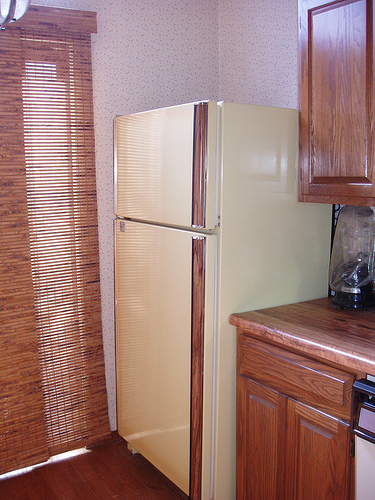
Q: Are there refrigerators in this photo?
A: Yes, there is a refrigerator.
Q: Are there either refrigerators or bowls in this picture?
A: Yes, there is a refrigerator.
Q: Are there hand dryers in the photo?
A: No, there are no hand dryers.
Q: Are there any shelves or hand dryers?
A: No, there are no hand dryers or shelves.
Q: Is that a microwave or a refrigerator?
A: That is a refrigerator.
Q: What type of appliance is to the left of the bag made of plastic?
A: The appliance is a refrigerator.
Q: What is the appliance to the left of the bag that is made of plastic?
A: The appliance is a refrigerator.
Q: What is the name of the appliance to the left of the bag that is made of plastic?
A: The appliance is a refrigerator.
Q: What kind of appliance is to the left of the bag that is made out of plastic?
A: The appliance is a refrigerator.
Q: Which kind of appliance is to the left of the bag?
A: The appliance is a refrigerator.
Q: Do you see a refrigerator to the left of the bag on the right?
A: Yes, there is a refrigerator to the left of the bag.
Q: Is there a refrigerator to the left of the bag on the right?
A: Yes, there is a refrigerator to the left of the bag.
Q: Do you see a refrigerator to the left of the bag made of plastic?
A: Yes, there is a refrigerator to the left of the bag.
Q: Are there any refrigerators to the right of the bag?
A: No, the refrigerator is to the left of the bag.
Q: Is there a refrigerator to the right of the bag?
A: No, the refrigerator is to the left of the bag.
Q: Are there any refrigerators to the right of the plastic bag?
A: No, the refrigerator is to the left of the bag.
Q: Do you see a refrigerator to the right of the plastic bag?
A: No, the refrigerator is to the left of the bag.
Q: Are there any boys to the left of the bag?
A: No, there is a refrigerator to the left of the bag.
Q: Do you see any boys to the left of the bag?
A: No, there is a refrigerator to the left of the bag.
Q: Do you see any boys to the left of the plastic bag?
A: No, there is a refrigerator to the left of the bag.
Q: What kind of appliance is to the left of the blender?
A: The appliance is a refrigerator.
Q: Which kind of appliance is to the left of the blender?
A: The appliance is a refrigerator.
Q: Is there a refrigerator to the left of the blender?
A: Yes, there is a refrigerator to the left of the blender.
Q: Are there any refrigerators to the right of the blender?
A: No, the refrigerator is to the left of the blender.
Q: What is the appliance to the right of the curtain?
A: The appliance is a refrigerator.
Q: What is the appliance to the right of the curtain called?
A: The appliance is a refrigerator.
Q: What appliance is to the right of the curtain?
A: The appliance is a refrigerator.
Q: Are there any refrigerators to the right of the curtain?
A: Yes, there is a refrigerator to the right of the curtain.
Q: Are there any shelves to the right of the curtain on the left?
A: No, there is a refrigerator to the right of the curtain.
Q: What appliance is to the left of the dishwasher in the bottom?
A: The appliance is a refrigerator.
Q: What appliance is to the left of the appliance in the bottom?
A: The appliance is a refrigerator.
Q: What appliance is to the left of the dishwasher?
A: The appliance is a refrigerator.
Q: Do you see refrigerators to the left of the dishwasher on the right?
A: Yes, there is a refrigerator to the left of the dishwasher.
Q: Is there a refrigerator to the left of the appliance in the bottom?
A: Yes, there is a refrigerator to the left of the dishwasher.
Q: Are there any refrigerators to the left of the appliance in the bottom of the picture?
A: Yes, there is a refrigerator to the left of the dishwasher.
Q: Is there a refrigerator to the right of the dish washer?
A: No, the refrigerator is to the left of the dish washer.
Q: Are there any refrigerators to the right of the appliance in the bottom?
A: No, the refrigerator is to the left of the dish washer.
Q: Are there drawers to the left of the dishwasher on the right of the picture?
A: No, there is a refrigerator to the left of the dishwasher.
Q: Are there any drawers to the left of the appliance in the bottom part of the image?
A: No, there is a refrigerator to the left of the dishwasher.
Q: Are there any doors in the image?
A: Yes, there is a door.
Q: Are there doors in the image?
A: Yes, there is a door.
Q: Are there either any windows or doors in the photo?
A: Yes, there is a door.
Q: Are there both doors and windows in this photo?
A: Yes, there are both a door and a window.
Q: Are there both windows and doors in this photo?
A: Yes, there are both a door and a window.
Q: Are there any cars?
A: No, there are no cars.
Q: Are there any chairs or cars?
A: No, there are no cars or chairs.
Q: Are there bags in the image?
A: Yes, there is a bag.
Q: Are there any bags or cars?
A: Yes, there is a bag.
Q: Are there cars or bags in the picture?
A: Yes, there is a bag.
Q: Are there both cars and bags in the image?
A: No, there is a bag but no cars.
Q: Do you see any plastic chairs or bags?
A: Yes, there is a plastic bag.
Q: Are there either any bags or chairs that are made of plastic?
A: Yes, the bag is made of plastic.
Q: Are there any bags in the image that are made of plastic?
A: Yes, there is a bag that is made of plastic.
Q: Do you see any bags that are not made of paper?
A: Yes, there is a bag that is made of plastic.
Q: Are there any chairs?
A: No, there are no chairs.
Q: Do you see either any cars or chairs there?
A: No, there are no chairs or cars.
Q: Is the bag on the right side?
A: Yes, the bag is on the right of the image.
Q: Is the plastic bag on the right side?
A: Yes, the bag is on the right of the image.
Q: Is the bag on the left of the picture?
A: No, the bag is on the right of the image.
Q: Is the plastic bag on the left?
A: No, the bag is on the right of the image.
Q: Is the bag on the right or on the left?
A: The bag is on the right of the image.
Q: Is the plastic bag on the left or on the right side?
A: The bag is on the right of the image.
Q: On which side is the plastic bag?
A: The bag is on the right of the image.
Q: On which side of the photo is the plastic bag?
A: The bag is on the right of the image.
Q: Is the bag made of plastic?
A: Yes, the bag is made of plastic.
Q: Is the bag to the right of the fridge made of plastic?
A: Yes, the bag is made of plastic.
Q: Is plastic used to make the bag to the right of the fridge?
A: Yes, the bag is made of plastic.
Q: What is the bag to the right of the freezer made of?
A: The bag is made of plastic.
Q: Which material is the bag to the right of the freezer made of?
A: The bag is made of plastic.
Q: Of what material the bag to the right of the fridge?
A: The bag is made of plastic.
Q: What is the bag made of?
A: The bag is made of plastic.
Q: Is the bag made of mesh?
A: No, the bag is made of plastic.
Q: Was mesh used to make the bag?
A: No, the bag is made of plastic.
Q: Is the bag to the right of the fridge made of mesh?
A: No, the bag is made of plastic.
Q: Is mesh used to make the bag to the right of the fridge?
A: No, the bag is made of plastic.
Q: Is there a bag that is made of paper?
A: No, there is a bag but it is made of plastic.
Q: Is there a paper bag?
A: No, there is a bag but it is made of plastic.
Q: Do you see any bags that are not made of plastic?
A: No, there is a bag but it is made of plastic.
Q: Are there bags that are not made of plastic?
A: No, there is a bag but it is made of plastic.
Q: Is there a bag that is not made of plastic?
A: No, there is a bag but it is made of plastic.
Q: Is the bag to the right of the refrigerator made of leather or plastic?
A: The bag is made of plastic.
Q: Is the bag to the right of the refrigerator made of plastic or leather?
A: The bag is made of plastic.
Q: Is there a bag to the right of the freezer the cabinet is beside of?
A: Yes, there is a bag to the right of the refrigerator.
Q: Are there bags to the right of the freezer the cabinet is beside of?
A: Yes, there is a bag to the right of the refrigerator.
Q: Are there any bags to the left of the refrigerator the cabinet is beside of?
A: No, the bag is to the right of the refrigerator.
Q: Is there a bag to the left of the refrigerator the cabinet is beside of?
A: No, the bag is to the right of the refrigerator.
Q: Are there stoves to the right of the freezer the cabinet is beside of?
A: No, there is a bag to the right of the fridge.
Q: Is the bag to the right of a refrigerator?
A: Yes, the bag is to the right of a refrigerator.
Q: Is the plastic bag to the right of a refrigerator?
A: Yes, the bag is to the right of a refrigerator.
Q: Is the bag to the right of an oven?
A: No, the bag is to the right of a refrigerator.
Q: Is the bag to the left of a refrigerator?
A: No, the bag is to the right of a refrigerator.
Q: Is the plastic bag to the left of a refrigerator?
A: No, the bag is to the right of a refrigerator.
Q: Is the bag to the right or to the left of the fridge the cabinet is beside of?
A: The bag is to the right of the refrigerator.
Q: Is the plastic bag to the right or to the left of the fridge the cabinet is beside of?
A: The bag is to the right of the refrigerator.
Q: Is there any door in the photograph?
A: Yes, there is a door.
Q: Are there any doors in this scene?
A: Yes, there is a door.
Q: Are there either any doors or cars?
A: Yes, there is a door.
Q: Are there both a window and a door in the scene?
A: Yes, there are both a door and a window.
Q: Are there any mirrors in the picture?
A: No, there are no mirrors.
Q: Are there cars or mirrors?
A: No, there are no mirrors or cars.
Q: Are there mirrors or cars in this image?
A: No, there are no mirrors or cars.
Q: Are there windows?
A: Yes, there is a window.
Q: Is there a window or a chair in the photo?
A: Yes, there is a window.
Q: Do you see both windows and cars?
A: No, there is a window but no cars.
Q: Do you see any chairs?
A: No, there are no chairs.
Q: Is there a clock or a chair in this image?
A: No, there are no chairs or clocks.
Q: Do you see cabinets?
A: Yes, there is a cabinet.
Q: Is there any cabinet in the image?
A: Yes, there is a cabinet.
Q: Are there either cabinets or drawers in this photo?
A: Yes, there is a cabinet.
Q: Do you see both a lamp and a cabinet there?
A: No, there is a cabinet but no lamps.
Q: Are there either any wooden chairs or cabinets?
A: Yes, there is a wood cabinet.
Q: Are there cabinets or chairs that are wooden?
A: Yes, the cabinet is wooden.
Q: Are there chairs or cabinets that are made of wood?
A: Yes, the cabinet is made of wood.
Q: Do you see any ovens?
A: No, there are no ovens.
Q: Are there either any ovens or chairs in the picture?
A: No, there are no ovens or chairs.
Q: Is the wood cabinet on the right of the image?
A: Yes, the cabinet is on the right of the image.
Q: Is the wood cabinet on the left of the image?
A: No, the cabinet is on the right of the image.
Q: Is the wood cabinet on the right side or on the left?
A: The cabinet is on the right of the image.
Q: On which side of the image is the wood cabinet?
A: The cabinet is on the right of the image.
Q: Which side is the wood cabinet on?
A: The cabinet is on the right of the image.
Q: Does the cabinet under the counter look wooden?
A: Yes, the cabinet is wooden.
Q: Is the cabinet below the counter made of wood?
A: Yes, the cabinet is made of wood.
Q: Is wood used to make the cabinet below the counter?
A: Yes, the cabinet is made of wood.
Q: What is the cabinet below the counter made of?
A: The cabinet is made of wood.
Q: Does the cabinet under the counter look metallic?
A: No, the cabinet is wooden.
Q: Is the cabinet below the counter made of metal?
A: No, the cabinet is made of wood.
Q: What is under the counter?
A: The cabinet is under the counter.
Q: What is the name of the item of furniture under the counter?
A: The piece of furniture is a cabinet.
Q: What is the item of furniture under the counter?
A: The piece of furniture is a cabinet.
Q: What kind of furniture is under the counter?
A: The piece of furniture is a cabinet.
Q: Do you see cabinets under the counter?
A: Yes, there is a cabinet under the counter.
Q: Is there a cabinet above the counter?
A: No, the cabinet is under the counter.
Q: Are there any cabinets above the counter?
A: No, the cabinet is under the counter.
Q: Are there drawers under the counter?
A: No, there is a cabinet under the counter.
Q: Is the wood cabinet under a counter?
A: Yes, the cabinet is under a counter.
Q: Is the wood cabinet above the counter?
A: No, the cabinet is under the counter.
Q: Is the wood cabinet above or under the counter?
A: The cabinet is under the counter.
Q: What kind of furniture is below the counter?
A: The piece of furniture is a cabinet.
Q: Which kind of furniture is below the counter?
A: The piece of furniture is a cabinet.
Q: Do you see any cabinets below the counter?
A: Yes, there is a cabinet below the counter.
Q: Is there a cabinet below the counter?
A: Yes, there is a cabinet below the counter.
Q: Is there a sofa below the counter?
A: No, there is a cabinet below the counter.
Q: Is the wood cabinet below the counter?
A: Yes, the cabinet is below the counter.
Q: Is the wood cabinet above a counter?
A: No, the cabinet is below a counter.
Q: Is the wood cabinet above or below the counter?
A: The cabinet is below the counter.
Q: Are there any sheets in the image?
A: No, there are no sheets.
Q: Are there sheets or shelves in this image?
A: No, there are no sheets or shelves.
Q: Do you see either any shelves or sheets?
A: No, there are no sheets or shelves.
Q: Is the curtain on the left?
A: Yes, the curtain is on the left of the image.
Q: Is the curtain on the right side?
A: No, the curtain is on the left of the image.